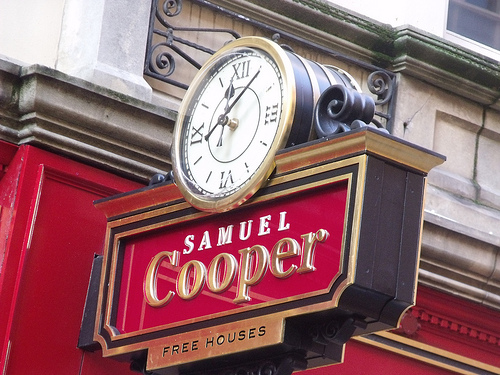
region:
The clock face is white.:
[163, 39, 295, 191]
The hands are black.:
[185, 61, 260, 138]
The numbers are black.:
[159, 45, 304, 191]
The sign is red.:
[111, 176, 346, 326]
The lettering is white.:
[168, 214, 303, 248]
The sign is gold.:
[136, 320, 305, 373]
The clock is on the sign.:
[35, 24, 462, 374]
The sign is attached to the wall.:
[4, 2, 489, 367]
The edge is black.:
[25, 9, 497, 323]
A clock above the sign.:
[174, 34, 270, 189]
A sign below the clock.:
[107, 207, 383, 314]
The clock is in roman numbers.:
[174, 61, 289, 143]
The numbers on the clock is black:
[222, 57, 303, 124]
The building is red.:
[19, 108, 87, 306]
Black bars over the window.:
[147, 4, 403, 96]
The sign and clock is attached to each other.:
[65, 25, 406, 340]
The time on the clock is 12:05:
[199, 25, 271, 164]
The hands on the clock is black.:
[202, 52, 253, 152]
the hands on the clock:
[203, 68, 260, 145]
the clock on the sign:
[171, 36, 296, 212]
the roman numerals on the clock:
[189, 59, 278, 189]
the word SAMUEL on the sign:
[182, 210, 288, 252]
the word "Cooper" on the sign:
[142, 228, 329, 306]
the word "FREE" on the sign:
[161, 338, 198, 355]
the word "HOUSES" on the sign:
[205, 325, 266, 347]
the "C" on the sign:
[140, 249, 179, 307]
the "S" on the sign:
[182, 234, 194, 254]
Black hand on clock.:
[233, 76, 278, 113]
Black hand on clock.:
[215, 80, 241, 140]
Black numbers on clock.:
[196, 85, 276, 187]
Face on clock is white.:
[187, 80, 258, 197]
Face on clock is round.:
[189, 85, 262, 200]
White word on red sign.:
[173, 228, 302, 251]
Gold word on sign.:
[131, 251, 349, 294]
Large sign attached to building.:
[101, 209, 411, 310]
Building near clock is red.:
[23, 214, 64, 333]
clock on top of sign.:
[173, 37, 295, 207]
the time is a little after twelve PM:
[195, 53, 270, 157]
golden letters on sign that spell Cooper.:
[133, 233, 333, 310]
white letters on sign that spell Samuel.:
[181, 213, 291, 258]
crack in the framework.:
[468, 100, 495, 201]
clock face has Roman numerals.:
[185, 55, 282, 195]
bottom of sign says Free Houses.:
[153, 323, 271, 361]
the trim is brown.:
[3, 59, 181, 163]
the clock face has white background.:
[183, 60, 283, 190]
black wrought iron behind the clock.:
[149, 28, 394, 121]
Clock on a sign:
[121, 28, 358, 203]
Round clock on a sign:
[157, 43, 318, 193]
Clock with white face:
[171, 42, 301, 204]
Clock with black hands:
[183, 44, 312, 204]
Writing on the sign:
[128, 220, 325, 307]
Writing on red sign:
[133, 207, 338, 301]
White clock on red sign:
[152, 49, 324, 201]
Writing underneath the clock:
[140, 210, 342, 293]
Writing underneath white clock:
[124, 214, 320, 304]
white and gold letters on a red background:
[112, 176, 348, 341]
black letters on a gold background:
[148, 324, 274, 364]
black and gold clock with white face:
[170, 34, 368, 213]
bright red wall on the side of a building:
[0, 138, 499, 374]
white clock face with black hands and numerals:
[178, 42, 285, 205]